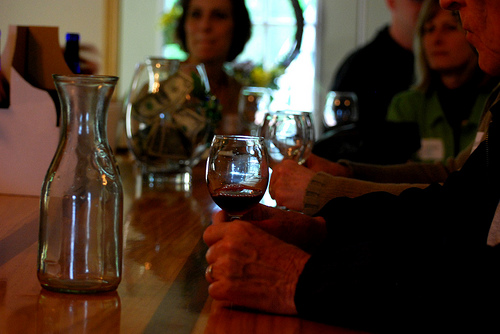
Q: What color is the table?
A: Brown.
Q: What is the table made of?
A: Wood.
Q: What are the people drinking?
A: Wine.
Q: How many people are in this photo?
A: Four.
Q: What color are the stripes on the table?
A: Black.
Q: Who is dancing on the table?
A: No one.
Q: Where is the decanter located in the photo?
A: Bottom left.